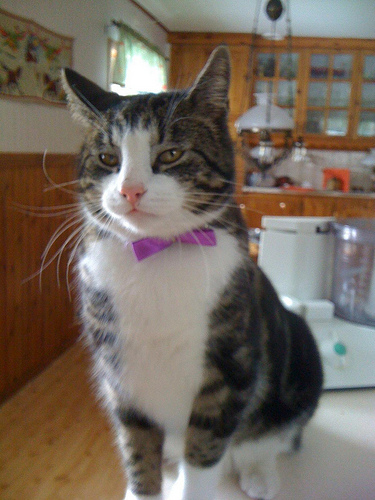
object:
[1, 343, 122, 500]
floors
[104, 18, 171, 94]
curtains window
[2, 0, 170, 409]
wall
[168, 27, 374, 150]
cabinets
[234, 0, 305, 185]
fixture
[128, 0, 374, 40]
ceiling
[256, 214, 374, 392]
blender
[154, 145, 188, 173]
eye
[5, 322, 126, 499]
table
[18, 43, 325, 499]
cat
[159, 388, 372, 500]
table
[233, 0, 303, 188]
lamp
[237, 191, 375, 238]
kitchen cabinets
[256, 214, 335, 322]
processor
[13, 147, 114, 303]
whiskers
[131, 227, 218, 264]
bow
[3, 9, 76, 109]
picture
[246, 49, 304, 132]
window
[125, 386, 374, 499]
counter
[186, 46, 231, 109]
ear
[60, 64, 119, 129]
ear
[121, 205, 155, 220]
mouth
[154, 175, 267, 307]
whiskers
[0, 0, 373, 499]
kitchen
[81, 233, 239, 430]
chest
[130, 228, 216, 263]
ribbon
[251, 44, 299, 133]
glass door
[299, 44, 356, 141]
glass door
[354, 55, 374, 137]
glass door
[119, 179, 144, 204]
nose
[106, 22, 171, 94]
curtain